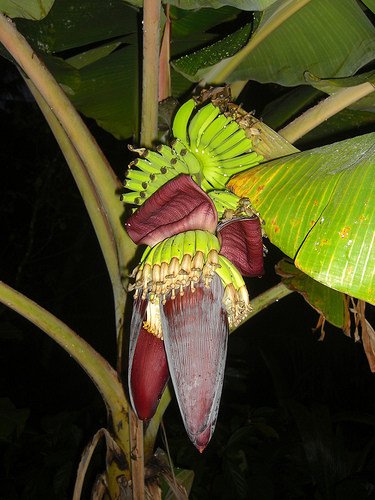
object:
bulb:
[161, 272, 229, 452]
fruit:
[169, 93, 199, 143]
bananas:
[143, 148, 171, 173]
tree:
[4, 0, 375, 500]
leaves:
[225, 125, 374, 302]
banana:
[169, 91, 190, 142]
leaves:
[58, 417, 115, 496]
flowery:
[163, 273, 235, 461]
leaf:
[222, 129, 373, 318]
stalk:
[124, 405, 148, 495]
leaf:
[170, 2, 374, 89]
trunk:
[92, 354, 172, 499]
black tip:
[170, 139, 176, 145]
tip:
[180, 148, 190, 158]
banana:
[180, 146, 200, 175]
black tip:
[141, 149, 148, 161]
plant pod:
[158, 285, 239, 455]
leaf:
[20, 309, 120, 389]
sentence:
[18, 28, 339, 437]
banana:
[218, 152, 261, 168]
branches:
[0, 0, 175, 311]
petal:
[131, 168, 220, 247]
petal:
[216, 213, 266, 280]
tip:
[119, 195, 125, 203]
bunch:
[118, 222, 227, 303]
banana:
[205, 229, 221, 267]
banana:
[195, 228, 208, 271]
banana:
[182, 226, 195, 277]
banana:
[169, 232, 186, 276]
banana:
[160, 233, 174, 285]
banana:
[154, 240, 165, 285]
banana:
[153, 240, 163, 282]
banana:
[131, 228, 222, 296]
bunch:
[167, 80, 269, 197]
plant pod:
[124, 174, 219, 252]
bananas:
[181, 148, 202, 179]